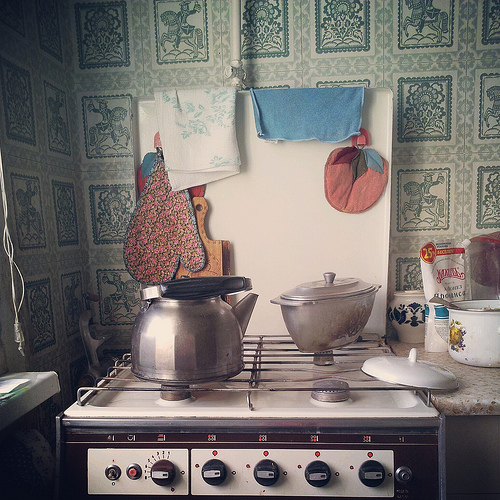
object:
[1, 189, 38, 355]
plastic control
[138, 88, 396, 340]
board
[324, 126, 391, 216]
holder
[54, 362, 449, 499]
oven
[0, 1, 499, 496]
kitchen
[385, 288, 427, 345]
tin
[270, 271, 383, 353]
container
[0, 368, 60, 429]
sink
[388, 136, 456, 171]
ground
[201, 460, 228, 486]
knob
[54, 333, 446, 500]
stove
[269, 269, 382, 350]
glassware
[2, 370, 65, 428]
window sill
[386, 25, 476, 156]
wallpaper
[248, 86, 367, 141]
blue towel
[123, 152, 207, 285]
holder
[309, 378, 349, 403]
burners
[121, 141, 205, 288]
oven mitt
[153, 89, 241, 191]
towel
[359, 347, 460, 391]
cover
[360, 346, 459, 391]
top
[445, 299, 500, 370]
pot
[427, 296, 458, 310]
utensil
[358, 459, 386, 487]
knobs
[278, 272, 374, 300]
lid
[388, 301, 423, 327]
pattern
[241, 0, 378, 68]
pattern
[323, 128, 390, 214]
designs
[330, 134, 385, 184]
designs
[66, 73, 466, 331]
wall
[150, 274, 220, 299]
lid